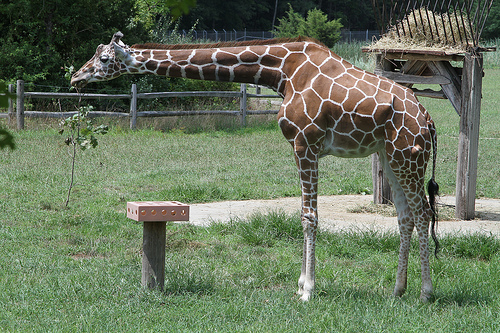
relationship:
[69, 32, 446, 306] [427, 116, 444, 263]
giraffe has tail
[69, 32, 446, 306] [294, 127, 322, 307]
giraffe has front leg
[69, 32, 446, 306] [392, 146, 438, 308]
giraffe has back left leg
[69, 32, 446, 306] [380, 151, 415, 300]
giraffe has back right leg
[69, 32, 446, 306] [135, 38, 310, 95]
giraffe has neck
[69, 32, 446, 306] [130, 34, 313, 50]
giraffe has mane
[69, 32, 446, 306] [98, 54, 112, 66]
giraffe has eye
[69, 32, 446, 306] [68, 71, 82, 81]
giraffe has nose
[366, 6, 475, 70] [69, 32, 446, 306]
hay behind giraffe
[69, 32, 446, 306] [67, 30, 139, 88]
giraffe has head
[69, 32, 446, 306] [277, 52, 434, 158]
giraffe has body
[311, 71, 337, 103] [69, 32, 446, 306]
spot on top of giraffe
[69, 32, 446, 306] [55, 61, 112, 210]
giraffe eating tree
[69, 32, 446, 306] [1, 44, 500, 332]
giraffe standing on grass